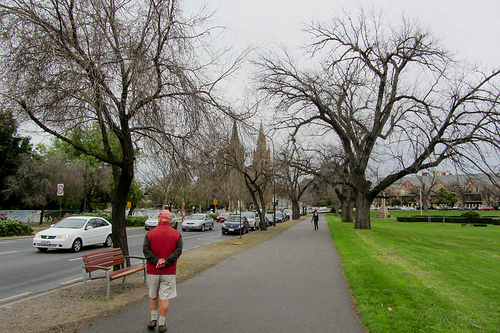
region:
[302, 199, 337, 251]
a person on a sidewalk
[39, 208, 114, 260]
vehicle on road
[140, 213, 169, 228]
vehicle on road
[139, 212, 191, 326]
The man is taking a walk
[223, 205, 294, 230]
The cars that are parked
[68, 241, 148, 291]
The bench next to the man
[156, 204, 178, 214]
The man is wearing a red hat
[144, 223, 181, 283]
The man is wearing a red vest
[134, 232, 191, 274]
The man's hands are crossed behind his back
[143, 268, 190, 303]
The man is wearing a short pant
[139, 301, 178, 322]
the man is wearing socks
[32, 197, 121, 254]
The white car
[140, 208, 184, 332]
man walking on the path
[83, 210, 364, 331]
a paved pathway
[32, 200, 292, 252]
cars on the street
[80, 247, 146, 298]
red bench next to the man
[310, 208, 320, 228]
a person walking in the distance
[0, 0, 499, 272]
large trees along the path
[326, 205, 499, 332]
a large grassy area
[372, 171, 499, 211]
a large building behind the grass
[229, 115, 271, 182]
a church behind the trees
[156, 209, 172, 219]
red hat on the man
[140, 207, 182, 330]
Man walking on sidewalk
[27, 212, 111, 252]
Car driving down street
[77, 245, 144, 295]
Park bench near sidewalk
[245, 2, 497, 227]
Large tree near sidewalk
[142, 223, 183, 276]
Man wearing red sweater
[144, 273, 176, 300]
Man wearing cargo shorts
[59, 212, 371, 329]
Black top sidewalk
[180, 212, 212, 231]
Car driving on busy street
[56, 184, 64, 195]
Street sign near street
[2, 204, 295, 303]
cars parked and moving down the street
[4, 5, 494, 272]
large leafless trees in park and along curb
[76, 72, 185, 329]
man walking near empty red bench by tree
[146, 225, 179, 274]
man wearing a red vest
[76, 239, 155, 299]
red bench on the sidewalk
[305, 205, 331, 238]
person walking on the sidewalk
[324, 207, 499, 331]
green grassy field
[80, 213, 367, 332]
sidewalk between the field and the road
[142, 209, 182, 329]
person in a red jacket on the sidewalk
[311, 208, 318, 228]
person wearing black on the sidewalk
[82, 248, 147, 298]
red bench next to the sidewalk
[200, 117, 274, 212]
large building in the background that looks like a church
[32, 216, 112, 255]
white car on the street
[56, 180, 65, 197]
white and red road sign on the far side of the road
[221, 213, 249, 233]
black car parked at the edge of the street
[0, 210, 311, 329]
strip of mostly dead grass between the sidewalk and the road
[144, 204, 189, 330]
a person walking on a sidewalk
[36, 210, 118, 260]
a car on a street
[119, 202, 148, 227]
a car on a street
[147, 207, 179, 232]
a car on a street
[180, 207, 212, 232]
a car on a street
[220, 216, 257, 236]
a car on a street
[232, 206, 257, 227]
a car on a street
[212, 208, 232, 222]
a car on a street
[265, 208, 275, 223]
a car on a street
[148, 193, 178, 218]
The man is wearing a red cap.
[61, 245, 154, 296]
A brown bench under the tree.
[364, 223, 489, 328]
The grass is green and trim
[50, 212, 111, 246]
A white car in the street.